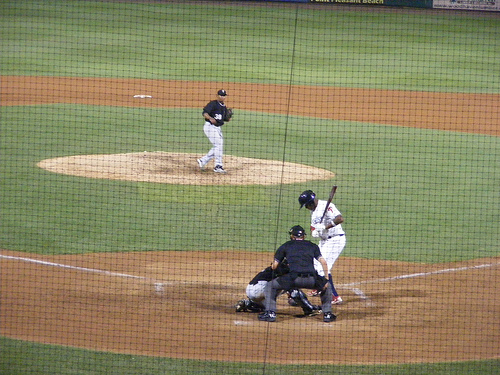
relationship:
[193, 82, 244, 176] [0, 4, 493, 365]
pitcher in baseball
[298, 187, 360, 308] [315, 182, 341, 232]
player with bat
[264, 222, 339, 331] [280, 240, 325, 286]
umpire wearing protection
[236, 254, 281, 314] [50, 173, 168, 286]
catcher on ground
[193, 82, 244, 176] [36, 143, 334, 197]
pitcher on mound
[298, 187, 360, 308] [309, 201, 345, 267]
player has uniform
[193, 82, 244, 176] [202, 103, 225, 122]
pitcher dressed in black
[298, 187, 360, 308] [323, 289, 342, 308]
player has shoes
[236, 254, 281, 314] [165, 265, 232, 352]
catcher in dirt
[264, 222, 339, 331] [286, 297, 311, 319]
umpire at home plate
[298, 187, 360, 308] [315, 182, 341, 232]
batter has a bat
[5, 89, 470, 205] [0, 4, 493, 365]
center of field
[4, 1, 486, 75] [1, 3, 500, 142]
outfield of field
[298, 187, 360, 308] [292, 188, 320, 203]
player has on helmet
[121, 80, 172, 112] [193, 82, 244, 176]
second base behind pitcher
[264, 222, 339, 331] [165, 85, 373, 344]
umpire calling play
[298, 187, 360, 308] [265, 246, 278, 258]
player looking down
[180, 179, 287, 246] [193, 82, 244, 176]
grass in front of pitcher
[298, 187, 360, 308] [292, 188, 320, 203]
player wearing helmet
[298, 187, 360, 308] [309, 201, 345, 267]
player with uniform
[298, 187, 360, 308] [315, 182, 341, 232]
player holding bat